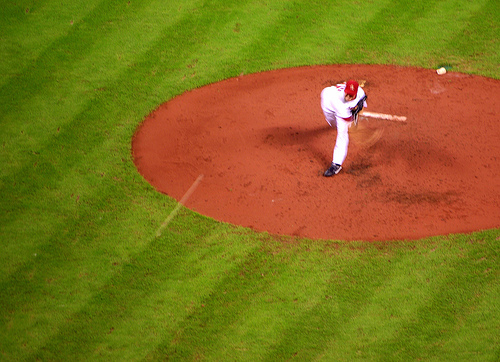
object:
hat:
[343, 78, 359, 96]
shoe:
[321, 162, 344, 177]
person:
[320, 76, 367, 178]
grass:
[0, 245, 499, 360]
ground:
[1, 0, 493, 360]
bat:
[358, 109, 408, 124]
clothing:
[321, 81, 369, 165]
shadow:
[265, 119, 333, 169]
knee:
[337, 132, 348, 144]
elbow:
[343, 116, 356, 122]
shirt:
[320, 81, 366, 123]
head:
[342, 79, 359, 102]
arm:
[336, 104, 357, 124]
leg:
[333, 119, 349, 164]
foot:
[323, 162, 342, 178]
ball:
[436, 66, 447, 75]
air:
[1, 2, 498, 107]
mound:
[133, 62, 497, 244]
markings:
[418, 75, 453, 98]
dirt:
[133, 65, 499, 243]